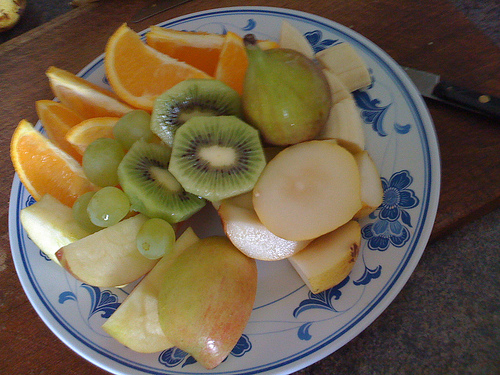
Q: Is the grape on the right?
A: No, the grape is on the left of the image.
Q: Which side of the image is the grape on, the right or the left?
A: The grape is on the left of the image.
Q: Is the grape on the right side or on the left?
A: The grape is on the left of the image.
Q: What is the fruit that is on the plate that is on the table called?
A: The fruit is a grape.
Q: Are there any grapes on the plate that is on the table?
A: Yes, there is a grape on the plate.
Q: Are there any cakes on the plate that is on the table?
A: No, there is a grape on the plate.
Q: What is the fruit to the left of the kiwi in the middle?
A: The fruit is a grape.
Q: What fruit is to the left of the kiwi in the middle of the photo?
A: The fruit is a grape.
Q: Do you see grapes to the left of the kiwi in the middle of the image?
A: Yes, there is a grape to the left of the kiwi.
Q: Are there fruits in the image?
A: Yes, there is a fruit.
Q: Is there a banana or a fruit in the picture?
A: Yes, there is a fruit.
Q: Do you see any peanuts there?
A: No, there are no peanuts.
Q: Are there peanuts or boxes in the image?
A: No, there are no peanuts or boxes.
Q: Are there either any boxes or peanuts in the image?
A: No, there are no peanuts or boxes.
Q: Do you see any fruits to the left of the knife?
A: Yes, there is a fruit to the left of the knife.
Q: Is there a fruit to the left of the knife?
A: Yes, there is a fruit to the left of the knife.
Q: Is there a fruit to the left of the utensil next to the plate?
A: Yes, there is a fruit to the left of the knife.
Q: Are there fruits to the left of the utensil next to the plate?
A: Yes, there is a fruit to the left of the knife.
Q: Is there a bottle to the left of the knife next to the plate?
A: No, there is a fruit to the left of the knife.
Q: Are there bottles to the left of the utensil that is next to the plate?
A: No, there is a fruit to the left of the knife.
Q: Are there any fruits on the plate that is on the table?
A: Yes, there is a fruit on the plate.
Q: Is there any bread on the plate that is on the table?
A: No, there is a fruit on the plate.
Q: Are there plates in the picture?
A: Yes, there is a plate.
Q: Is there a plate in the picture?
A: Yes, there is a plate.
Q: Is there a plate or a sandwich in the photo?
A: Yes, there is a plate.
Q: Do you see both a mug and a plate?
A: No, there is a plate but no mugs.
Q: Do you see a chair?
A: No, there are no chairs.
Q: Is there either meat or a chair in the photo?
A: No, there are no chairs or meat.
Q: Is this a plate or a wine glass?
A: This is a plate.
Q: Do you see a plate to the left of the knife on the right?
A: Yes, there is a plate to the left of the knife.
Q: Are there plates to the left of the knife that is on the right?
A: Yes, there is a plate to the left of the knife.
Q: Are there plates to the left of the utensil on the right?
A: Yes, there is a plate to the left of the knife.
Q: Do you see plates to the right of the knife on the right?
A: No, the plate is to the left of the knife.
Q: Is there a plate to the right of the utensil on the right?
A: No, the plate is to the left of the knife.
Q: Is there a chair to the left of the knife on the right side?
A: No, there is a plate to the left of the knife.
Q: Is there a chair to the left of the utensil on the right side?
A: No, there is a plate to the left of the knife.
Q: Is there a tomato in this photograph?
A: No, there are no tomatoes.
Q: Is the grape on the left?
A: Yes, the grape is on the left of the image.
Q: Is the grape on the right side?
A: No, the grape is on the left of the image.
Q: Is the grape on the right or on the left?
A: The grape is on the left of the image.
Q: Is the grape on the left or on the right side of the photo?
A: The grape is on the left of the image.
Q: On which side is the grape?
A: The grape is on the left of the image.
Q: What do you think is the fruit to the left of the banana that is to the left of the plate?
A: The fruit is a grape.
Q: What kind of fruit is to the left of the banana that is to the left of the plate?
A: The fruit is a grape.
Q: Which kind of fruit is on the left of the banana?
A: The fruit is a grape.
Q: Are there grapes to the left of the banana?
A: Yes, there is a grape to the left of the banana.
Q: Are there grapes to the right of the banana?
A: No, the grape is to the left of the banana.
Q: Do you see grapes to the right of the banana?
A: No, the grape is to the left of the banana.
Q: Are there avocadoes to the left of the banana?
A: No, there is a grape to the left of the banana.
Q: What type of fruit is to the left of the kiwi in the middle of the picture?
A: The fruit is a grape.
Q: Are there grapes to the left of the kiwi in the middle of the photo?
A: Yes, there is a grape to the left of the kiwi.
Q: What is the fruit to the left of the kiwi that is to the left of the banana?
A: The fruit is a grape.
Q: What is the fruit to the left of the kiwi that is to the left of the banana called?
A: The fruit is a grape.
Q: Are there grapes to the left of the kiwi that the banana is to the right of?
A: Yes, there is a grape to the left of the kiwi.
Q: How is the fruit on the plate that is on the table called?
A: The fruit is a grape.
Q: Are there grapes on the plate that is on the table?
A: Yes, there is a grape on the plate.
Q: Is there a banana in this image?
A: Yes, there is a banana.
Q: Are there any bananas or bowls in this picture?
A: Yes, there is a banana.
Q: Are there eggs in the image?
A: No, there are no eggs.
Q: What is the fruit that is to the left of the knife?
A: The fruit is a banana.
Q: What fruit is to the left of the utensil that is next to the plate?
A: The fruit is a banana.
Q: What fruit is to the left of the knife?
A: The fruit is a banana.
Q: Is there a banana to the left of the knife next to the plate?
A: Yes, there is a banana to the left of the knife.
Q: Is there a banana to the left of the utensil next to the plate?
A: Yes, there is a banana to the left of the knife.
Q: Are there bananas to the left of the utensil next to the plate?
A: Yes, there is a banana to the left of the knife.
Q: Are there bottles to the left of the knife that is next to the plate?
A: No, there is a banana to the left of the knife.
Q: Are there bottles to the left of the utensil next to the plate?
A: No, there is a banana to the left of the knife.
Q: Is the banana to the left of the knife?
A: Yes, the banana is to the left of the knife.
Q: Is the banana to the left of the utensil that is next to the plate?
A: Yes, the banana is to the left of the knife.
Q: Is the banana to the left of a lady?
A: No, the banana is to the left of the knife.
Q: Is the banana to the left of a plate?
A: Yes, the banana is to the left of a plate.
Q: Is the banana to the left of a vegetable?
A: No, the banana is to the left of a plate.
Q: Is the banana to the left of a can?
A: No, the banana is to the left of the plate.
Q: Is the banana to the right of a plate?
A: No, the banana is to the left of a plate.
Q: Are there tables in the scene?
A: Yes, there is a table.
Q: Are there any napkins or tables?
A: Yes, there is a table.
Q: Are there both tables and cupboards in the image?
A: No, there is a table but no cupboards.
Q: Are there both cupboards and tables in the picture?
A: No, there is a table but no cupboards.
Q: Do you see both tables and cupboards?
A: No, there is a table but no cupboards.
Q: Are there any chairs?
A: No, there are no chairs.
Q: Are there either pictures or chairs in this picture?
A: No, there are no chairs or pictures.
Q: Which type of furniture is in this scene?
A: The furniture is a table.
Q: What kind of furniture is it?
A: The piece of furniture is a table.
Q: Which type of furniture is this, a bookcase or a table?
A: That is a table.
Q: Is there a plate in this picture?
A: Yes, there is a plate.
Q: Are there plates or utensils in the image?
A: Yes, there is a plate.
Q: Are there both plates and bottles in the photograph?
A: No, there is a plate but no bottles.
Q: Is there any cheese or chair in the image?
A: No, there are no chairs or cheese.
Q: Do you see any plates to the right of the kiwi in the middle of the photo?
A: Yes, there is a plate to the right of the kiwi.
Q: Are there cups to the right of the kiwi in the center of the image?
A: No, there is a plate to the right of the kiwi.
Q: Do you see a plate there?
A: Yes, there is a plate.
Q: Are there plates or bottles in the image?
A: Yes, there is a plate.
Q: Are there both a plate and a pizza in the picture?
A: No, there is a plate but no pizzas.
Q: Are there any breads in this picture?
A: No, there are no breads.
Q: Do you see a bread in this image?
A: No, there is no breads.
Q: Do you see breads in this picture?
A: No, there are no breads.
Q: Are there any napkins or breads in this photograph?
A: No, there are no breads or napkins.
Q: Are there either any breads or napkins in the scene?
A: No, there are no breads or napkins.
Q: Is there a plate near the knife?
A: Yes, there is a plate near the knife.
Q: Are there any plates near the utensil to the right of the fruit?
A: Yes, there is a plate near the knife.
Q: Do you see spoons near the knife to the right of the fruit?
A: No, there is a plate near the knife.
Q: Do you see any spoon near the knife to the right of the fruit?
A: No, there is a plate near the knife.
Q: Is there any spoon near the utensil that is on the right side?
A: No, there is a plate near the knife.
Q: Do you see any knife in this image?
A: Yes, there is a knife.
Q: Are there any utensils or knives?
A: Yes, there is a knife.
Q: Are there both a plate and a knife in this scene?
A: Yes, there are both a knife and a plate.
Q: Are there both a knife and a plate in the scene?
A: Yes, there are both a knife and a plate.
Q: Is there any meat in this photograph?
A: No, there is no meat.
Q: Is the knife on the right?
A: Yes, the knife is on the right of the image.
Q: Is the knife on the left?
A: No, the knife is on the right of the image.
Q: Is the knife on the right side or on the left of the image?
A: The knife is on the right of the image.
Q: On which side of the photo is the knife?
A: The knife is on the right of the image.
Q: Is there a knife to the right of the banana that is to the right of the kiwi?
A: Yes, there is a knife to the right of the banana.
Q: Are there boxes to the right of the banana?
A: No, there is a knife to the right of the banana.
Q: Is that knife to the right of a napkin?
A: No, the knife is to the right of the banana.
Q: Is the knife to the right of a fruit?
A: Yes, the knife is to the right of a fruit.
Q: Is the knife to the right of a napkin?
A: No, the knife is to the right of a fruit.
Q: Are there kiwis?
A: Yes, there is a kiwi.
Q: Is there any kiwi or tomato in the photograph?
A: Yes, there is a kiwi.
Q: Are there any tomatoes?
A: No, there are no tomatoes.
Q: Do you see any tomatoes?
A: No, there are no tomatoes.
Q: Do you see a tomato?
A: No, there are no tomatoes.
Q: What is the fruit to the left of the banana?
A: The fruit is a kiwi.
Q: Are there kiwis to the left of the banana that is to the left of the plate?
A: Yes, there is a kiwi to the left of the banana.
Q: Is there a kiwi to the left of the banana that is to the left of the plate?
A: Yes, there is a kiwi to the left of the banana.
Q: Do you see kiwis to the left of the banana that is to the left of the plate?
A: Yes, there is a kiwi to the left of the banana.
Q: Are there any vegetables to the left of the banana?
A: No, there is a kiwi to the left of the banana.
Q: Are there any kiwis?
A: Yes, there is a kiwi.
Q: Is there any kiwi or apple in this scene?
A: Yes, there is a kiwi.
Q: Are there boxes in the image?
A: No, there are no boxes.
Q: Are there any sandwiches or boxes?
A: No, there are no boxes or sandwiches.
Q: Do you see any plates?
A: Yes, there is a plate.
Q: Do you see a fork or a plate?
A: Yes, there is a plate.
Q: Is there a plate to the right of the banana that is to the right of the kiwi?
A: Yes, there is a plate to the right of the banana.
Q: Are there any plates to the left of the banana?
A: No, the plate is to the right of the banana.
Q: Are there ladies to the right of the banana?
A: No, there is a plate to the right of the banana.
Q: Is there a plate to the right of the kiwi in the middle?
A: Yes, there is a plate to the right of the kiwi.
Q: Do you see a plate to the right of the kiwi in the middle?
A: Yes, there is a plate to the right of the kiwi.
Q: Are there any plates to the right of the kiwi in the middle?
A: Yes, there is a plate to the right of the kiwi.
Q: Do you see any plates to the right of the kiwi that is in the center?
A: Yes, there is a plate to the right of the kiwi.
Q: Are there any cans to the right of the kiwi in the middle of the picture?
A: No, there is a plate to the right of the kiwi.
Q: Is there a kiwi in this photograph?
A: Yes, there is a kiwi.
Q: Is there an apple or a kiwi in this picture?
A: Yes, there is a kiwi.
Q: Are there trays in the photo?
A: No, there are no trays.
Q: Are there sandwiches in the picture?
A: No, there are no sandwiches.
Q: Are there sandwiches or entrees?
A: No, there are no sandwiches or entrees.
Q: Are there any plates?
A: Yes, there is a plate.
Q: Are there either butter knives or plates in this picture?
A: Yes, there is a plate.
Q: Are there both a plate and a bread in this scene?
A: No, there is a plate but no breads.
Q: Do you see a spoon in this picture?
A: No, there are no spoons.